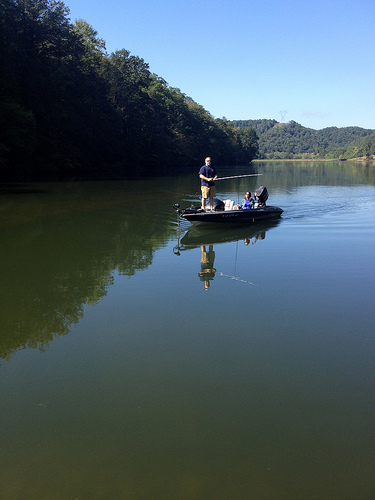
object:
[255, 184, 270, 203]
trolling motor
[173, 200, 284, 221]
boat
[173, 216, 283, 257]
reflection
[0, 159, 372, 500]
water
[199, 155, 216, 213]
man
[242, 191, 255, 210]
woman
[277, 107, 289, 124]
utility pole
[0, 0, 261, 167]
trees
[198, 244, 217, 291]
reflection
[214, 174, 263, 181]
fishing pole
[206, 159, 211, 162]
sunglasses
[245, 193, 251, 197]
sunglasses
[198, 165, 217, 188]
shirt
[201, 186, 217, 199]
shorts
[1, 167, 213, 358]
reflection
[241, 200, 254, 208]
shirt